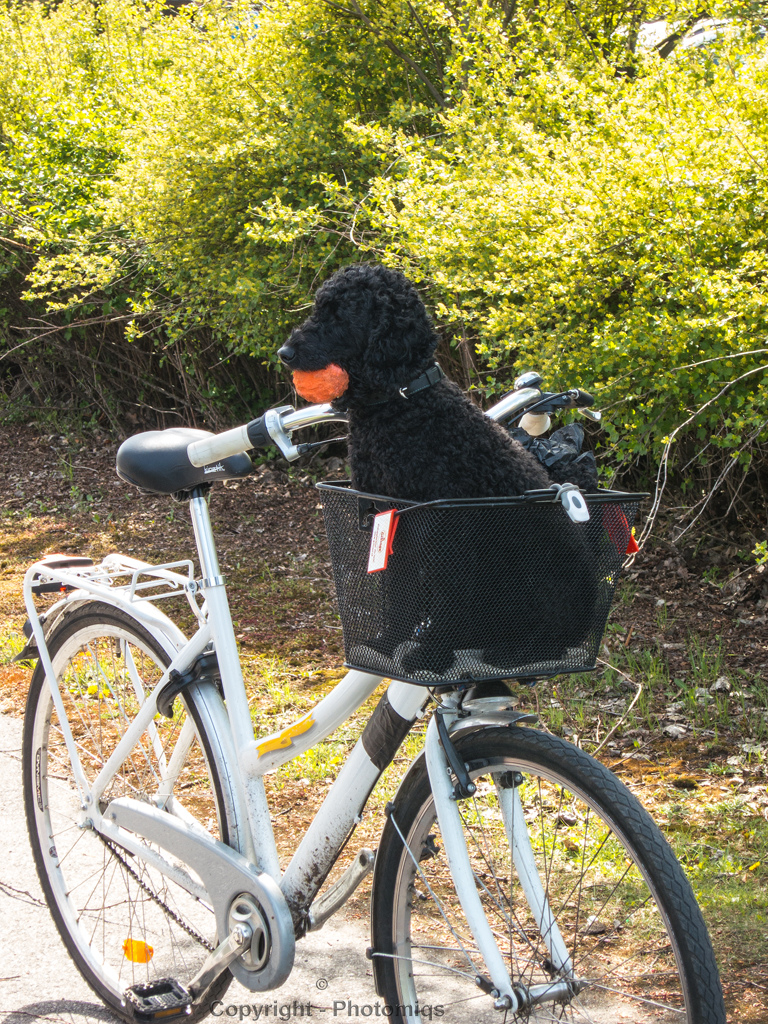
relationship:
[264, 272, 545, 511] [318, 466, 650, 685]
dog inside of basket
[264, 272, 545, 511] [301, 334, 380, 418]
dog holding ball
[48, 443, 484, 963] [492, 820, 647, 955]
bike has spokes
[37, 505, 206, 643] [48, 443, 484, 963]
storage rack on bike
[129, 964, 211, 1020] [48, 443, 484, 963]
pedal on bike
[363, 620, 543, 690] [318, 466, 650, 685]
blanket in basket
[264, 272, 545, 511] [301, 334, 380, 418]
dog with ball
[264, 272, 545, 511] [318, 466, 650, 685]
dog in basket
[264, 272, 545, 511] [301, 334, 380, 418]
dog has ball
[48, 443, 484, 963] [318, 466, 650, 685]
bike has basket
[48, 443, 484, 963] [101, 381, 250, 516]
bike has seat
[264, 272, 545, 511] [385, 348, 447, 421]
dog has collar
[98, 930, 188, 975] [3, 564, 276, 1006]
reflector on wheel